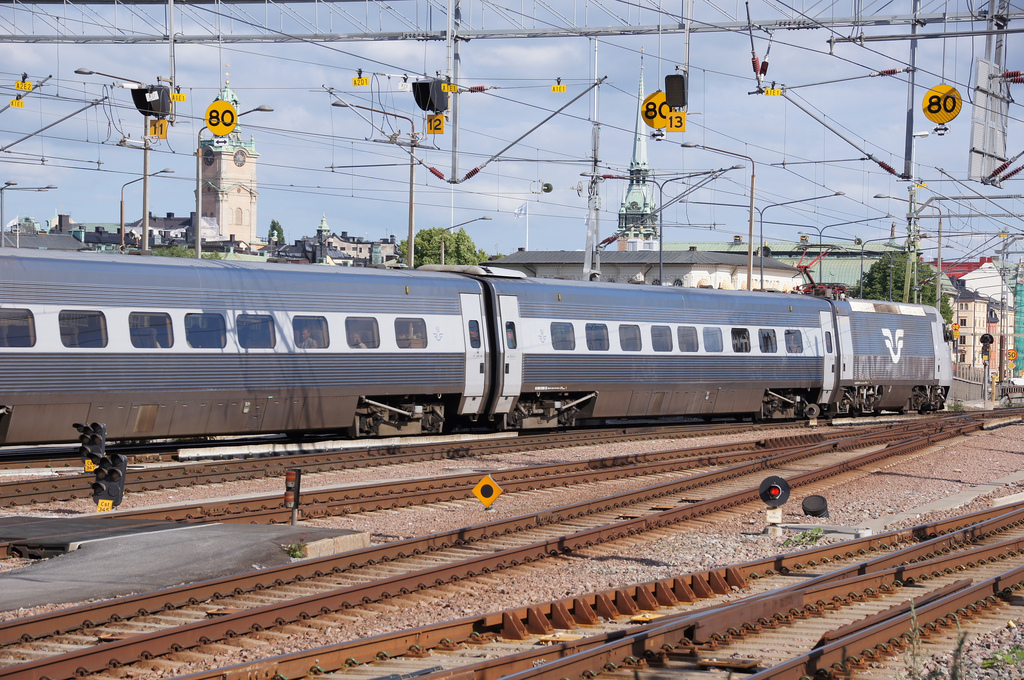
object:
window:
[129, 311, 175, 347]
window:
[184, 313, 227, 348]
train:
[0, 247, 952, 444]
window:
[236, 314, 275, 349]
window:
[58, 310, 107, 348]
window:
[0, 308, 38, 348]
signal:
[72, 423, 126, 512]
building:
[191, 63, 267, 263]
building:
[618, 44, 659, 251]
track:
[0, 406, 1024, 680]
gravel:
[0, 426, 826, 520]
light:
[759, 476, 791, 508]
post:
[764, 508, 781, 536]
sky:
[0, 0, 1022, 297]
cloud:
[362, 30, 579, 78]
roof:
[918, 257, 990, 279]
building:
[923, 256, 1011, 384]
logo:
[881, 328, 905, 364]